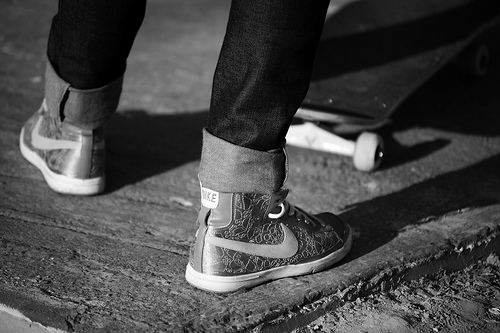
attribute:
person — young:
[20, 1, 355, 292]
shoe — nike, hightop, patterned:
[18, 98, 108, 196]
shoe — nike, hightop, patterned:
[182, 183, 353, 293]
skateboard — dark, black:
[283, 1, 498, 173]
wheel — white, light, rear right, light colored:
[353, 131, 384, 174]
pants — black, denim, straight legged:
[44, 1, 328, 194]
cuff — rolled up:
[44, 62, 125, 126]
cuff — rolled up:
[200, 126, 287, 195]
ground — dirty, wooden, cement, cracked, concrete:
[1, 0, 499, 333]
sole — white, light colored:
[19, 127, 104, 194]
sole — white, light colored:
[184, 224, 353, 291]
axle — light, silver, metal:
[286, 122, 357, 159]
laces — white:
[266, 200, 326, 230]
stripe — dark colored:
[76, 129, 94, 179]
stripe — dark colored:
[193, 205, 209, 273]